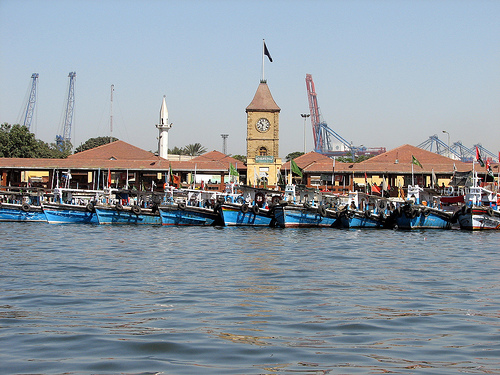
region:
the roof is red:
[369, 134, 441, 175]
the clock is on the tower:
[247, 109, 274, 138]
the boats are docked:
[23, 185, 474, 267]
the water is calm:
[150, 247, 342, 332]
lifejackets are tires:
[248, 204, 263, 217]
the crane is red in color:
[297, 78, 337, 138]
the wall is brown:
[247, 159, 281, 179]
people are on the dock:
[315, 174, 401, 196]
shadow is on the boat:
[236, 213, 262, 227]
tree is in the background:
[7, 126, 49, 156]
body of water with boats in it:
[12, 197, 492, 368]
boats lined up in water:
[2, 184, 499, 232]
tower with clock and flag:
[239, 38, 287, 183]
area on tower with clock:
[247, 112, 276, 139]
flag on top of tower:
[258, 37, 273, 81]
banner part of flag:
[258, 42, 280, 62]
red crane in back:
[298, 67, 328, 150]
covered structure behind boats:
[1, 158, 499, 191]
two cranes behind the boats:
[13, 63, 80, 148]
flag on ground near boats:
[406, 154, 423, 189]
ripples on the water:
[15, 234, 477, 333]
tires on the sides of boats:
[11, 202, 220, 214]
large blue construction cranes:
[26, 73, 83, 148]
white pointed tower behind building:
[154, 95, 178, 157]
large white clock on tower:
[245, 45, 280, 164]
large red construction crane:
[292, 72, 337, 149]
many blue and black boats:
[12, 188, 446, 233]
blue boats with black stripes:
[1, 195, 447, 236]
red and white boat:
[455, 198, 499, 230]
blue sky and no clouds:
[53, 34, 476, 124]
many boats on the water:
[31, 194, 450, 243]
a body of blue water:
[41, 210, 480, 330]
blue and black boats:
[33, 194, 471, 238]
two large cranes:
[21, 68, 100, 157]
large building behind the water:
[48, 145, 489, 183]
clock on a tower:
[244, 104, 286, 149]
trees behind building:
[0, 116, 211, 158]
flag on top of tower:
[221, 38, 299, 142]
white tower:
[151, 98, 178, 158]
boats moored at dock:
[3, 165, 499, 243]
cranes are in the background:
[10, 63, 198, 181]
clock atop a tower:
[250, 113, 273, 145]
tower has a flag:
[240, 26, 286, 90]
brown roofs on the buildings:
[3, 133, 473, 195]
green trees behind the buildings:
[3, 118, 121, 171]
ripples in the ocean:
[134, 275, 364, 372]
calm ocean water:
[105, 247, 365, 343]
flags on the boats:
[277, 151, 476, 182]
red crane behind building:
[293, 65, 346, 167]